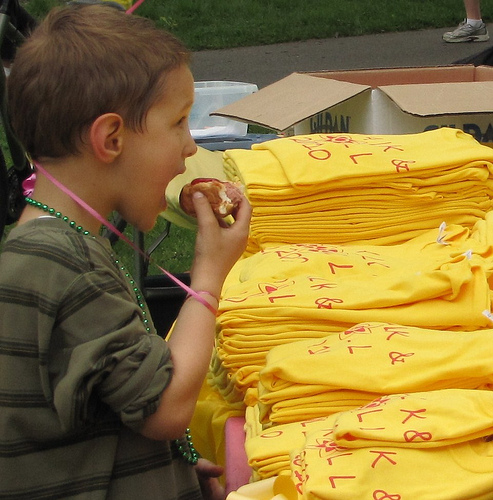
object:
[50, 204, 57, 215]
beads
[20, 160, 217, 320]
ribbon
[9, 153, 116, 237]
neck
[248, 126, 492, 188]
shirts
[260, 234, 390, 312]
writing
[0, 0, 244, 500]
boy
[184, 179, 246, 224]
hotdog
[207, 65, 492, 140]
box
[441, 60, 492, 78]
sneakers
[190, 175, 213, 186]
ketchup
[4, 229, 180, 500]
shirt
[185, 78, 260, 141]
container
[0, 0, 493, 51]
grass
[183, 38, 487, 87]
sidewalk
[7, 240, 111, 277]
stripes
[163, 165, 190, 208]
mouth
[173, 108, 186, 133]
eyes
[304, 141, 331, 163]
letters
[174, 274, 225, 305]
wrist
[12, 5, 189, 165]
hair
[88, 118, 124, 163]
ear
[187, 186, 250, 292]
hand